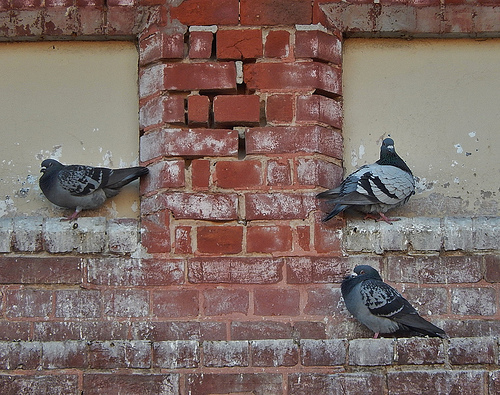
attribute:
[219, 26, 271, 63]
brick — cracked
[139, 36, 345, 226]
brick chimney — brick 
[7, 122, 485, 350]
birds — looking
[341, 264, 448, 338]
duck — beautiful 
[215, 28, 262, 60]
brick — red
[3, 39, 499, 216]
wall — grey 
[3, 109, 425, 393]
three pigeons — large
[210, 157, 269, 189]
brick — brick 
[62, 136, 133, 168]
paint — white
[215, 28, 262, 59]
tile — Red 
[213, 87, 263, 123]
brick — red 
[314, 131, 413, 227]
dove — grey 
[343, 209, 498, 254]
ledge — white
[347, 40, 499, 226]
wall — tan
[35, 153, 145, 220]
bird — gray, black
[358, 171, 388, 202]
tips — Black 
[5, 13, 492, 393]
wall — brick 